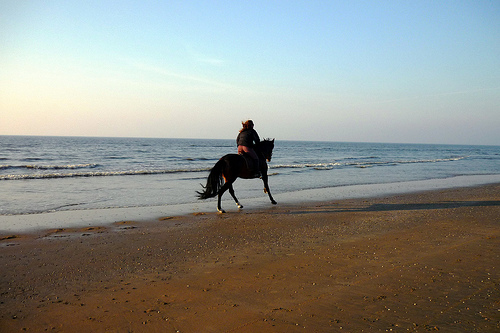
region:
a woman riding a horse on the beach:
[171, 106, 386, 238]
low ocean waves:
[7, 149, 152, 257]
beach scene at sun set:
[23, 108, 459, 265]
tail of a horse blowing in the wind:
[185, 142, 237, 206]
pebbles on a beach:
[52, 222, 427, 303]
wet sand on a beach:
[142, 233, 421, 310]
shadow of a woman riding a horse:
[289, 175, 486, 229]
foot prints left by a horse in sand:
[10, 204, 223, 234]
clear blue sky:
[77, 13, 440, 94]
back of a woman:
[228, 110, 273, 159]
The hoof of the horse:
[217, 207, 227, 219]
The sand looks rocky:
[90, 249, 261, 314]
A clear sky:
[42, 19, 289, 79]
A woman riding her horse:
[231, 119, 256, 158]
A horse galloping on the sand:
[214, 150, 316, 203]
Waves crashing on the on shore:
[27, 152, 135, 180]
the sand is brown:
[162, 258, 390, 305]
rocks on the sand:
[52, 249, 171, 291]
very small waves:
[22, 152, 189, 187]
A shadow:
[339, 189, 494, 232]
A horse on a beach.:
[193, 137, 278, 215]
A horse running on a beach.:
[193, 137, 277, 216]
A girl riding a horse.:
[191, 118, 277, 216]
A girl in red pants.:
[236, 120, 262, 175]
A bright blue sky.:
[2, 0, 499, 146]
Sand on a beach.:
[0, 181, 499, 329]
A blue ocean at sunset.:
[1, 134, 498, 235]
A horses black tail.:
[193, 160, 225, 201]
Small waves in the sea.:
[2, 152, 498, 181]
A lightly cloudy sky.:
[1, 48, 499, 145]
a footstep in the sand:
[223, 299, 240, 311]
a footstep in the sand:
[250, 284, 261, 299]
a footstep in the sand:
[198, 283, 210, 294]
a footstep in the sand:
[141, 307, 161, 319]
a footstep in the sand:
[157, 291, 177, 303]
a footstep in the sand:
[106, 292, 121, 303]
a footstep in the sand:
[66, 284, 86, 300]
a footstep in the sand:
[75, 300, 92, 310]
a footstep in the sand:
[11, 310, 28, 322]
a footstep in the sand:
[366, 292, 386, 302]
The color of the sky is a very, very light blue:
[395, 53, 432, 123]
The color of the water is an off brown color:
[118, 147, 147, 179]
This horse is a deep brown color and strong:
[216, 147, 296, 265]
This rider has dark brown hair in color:
[243, 123, 260, 125]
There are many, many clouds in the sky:
[175, 75, 191, 106]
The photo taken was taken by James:
[121, 37, 374, 314]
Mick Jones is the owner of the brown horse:
[165, 52, 345, 312]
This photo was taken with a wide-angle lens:
[153, 45, 388, 314]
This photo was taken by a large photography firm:
[155, 40, 395, 329]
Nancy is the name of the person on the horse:
[100, 17, 426, 312]